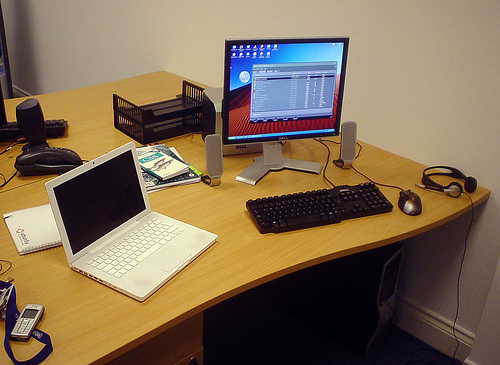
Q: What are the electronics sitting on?
A: Desk.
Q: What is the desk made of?
A: Wood.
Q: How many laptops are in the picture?
A: One.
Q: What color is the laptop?
A: White.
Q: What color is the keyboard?
A: Black.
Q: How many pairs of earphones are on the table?
A: One.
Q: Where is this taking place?
A: At an office.